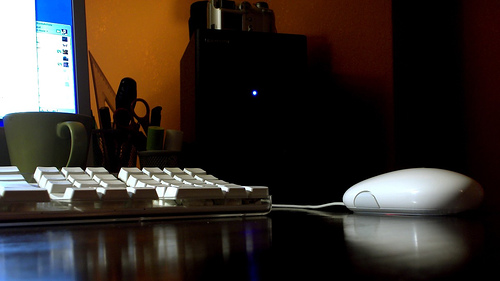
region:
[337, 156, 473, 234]
mouse on the table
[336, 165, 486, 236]
the mouse is white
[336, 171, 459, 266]
reflection of the mouse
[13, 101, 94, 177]
the mug is green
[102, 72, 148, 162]
tools in the cup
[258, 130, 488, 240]
this is a mouse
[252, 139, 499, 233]
the mouse is white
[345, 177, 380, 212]
grey button on mouse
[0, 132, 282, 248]
this is a keyboard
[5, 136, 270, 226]
the keyboard is white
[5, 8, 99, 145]
corner of a computer monitor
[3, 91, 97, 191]
this is a coffee mug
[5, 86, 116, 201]
the mug is green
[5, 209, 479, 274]
reflection on the desk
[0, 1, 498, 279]
room with dark corner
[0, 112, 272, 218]
coffee cup behind keyboard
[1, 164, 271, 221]
white square buttons of keyboard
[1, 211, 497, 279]
reflection on desk surface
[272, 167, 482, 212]
white computer mouse with attached wire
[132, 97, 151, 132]
silhouette of scissor handle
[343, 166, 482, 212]
light reflection on computer mouse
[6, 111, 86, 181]
curved handle on coffee cup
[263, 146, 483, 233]
this is a mouse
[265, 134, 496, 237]
the mouse is white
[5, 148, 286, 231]
this is a keyboard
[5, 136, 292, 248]
the keyboard is white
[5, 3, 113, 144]
the corner of a monitor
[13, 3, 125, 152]
the monitor is on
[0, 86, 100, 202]
the cup is green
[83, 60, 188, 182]
utensils next to monitor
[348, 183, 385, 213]
grey button on mouse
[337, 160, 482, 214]
White computer mouse.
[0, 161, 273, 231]
Computer keyboard.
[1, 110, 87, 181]
A green mug with the handle facing a keyboard..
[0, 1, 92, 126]
A computer monitor.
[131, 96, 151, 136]
Scissor's handle.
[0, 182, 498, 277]
A dark brown desk.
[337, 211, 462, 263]
The reflection of a computer mouse.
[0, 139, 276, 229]
keyboard on the table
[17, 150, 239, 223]
white keyboard on table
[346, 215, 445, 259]
reflection on the table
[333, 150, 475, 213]
mouse on the table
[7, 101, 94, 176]
green cup on the table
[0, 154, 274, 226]
keyboard on the desk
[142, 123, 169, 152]
highlighter in the cup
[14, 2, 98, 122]
computer monitor on the desk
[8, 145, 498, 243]
keyboard and mouse on the desk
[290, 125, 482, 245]
The mouse is white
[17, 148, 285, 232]
The keyboard is white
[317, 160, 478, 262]
The mouse is reflecting on the desk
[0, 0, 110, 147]
The screen is on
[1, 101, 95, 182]
The coffee mug is white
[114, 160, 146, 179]
The key is white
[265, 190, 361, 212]
The cord is white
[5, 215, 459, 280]
The desk is black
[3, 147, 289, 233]
The keyboard is on the desk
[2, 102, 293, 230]
The coffee mug is near the keyboard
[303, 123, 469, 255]
mouse on the table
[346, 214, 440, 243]
reflection of the mouse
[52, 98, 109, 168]
handle of the cup